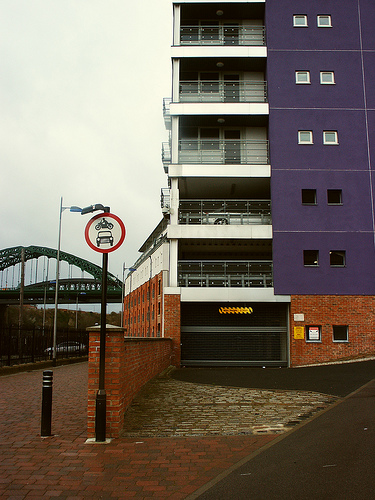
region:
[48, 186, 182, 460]
a street sign on a pole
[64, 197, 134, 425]
a street sign on a metal pole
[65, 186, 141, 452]
a sign on a metal pole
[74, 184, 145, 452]
a sign on a pole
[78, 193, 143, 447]
a circle street sign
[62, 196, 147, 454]
a circle street sign on a pole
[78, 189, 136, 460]
a circle street sign on a metal pole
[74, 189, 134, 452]
a circle sign on a pole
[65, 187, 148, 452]
a circle sign on a metal pole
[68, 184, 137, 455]
a circle sign outside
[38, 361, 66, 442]
a pole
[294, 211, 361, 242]
a purple building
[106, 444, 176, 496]
the ground is made of bricks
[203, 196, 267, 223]
a car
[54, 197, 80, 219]
a street light in the sky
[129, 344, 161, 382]
a brick wall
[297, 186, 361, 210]
windows on the building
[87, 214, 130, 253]
a traffic sign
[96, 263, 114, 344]
a black pole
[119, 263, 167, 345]
a brown and white building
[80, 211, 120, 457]
Street sign with a car and motorcycle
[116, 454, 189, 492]
Sidewalk made of brick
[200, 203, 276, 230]
Silver car parked in garage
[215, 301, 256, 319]
Hazard sign on parking garage door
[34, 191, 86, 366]
Lamp post on sidewalk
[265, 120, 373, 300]
Side of parking garage is purple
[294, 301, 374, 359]
First floor is made of brick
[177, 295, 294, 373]
Parking garage door entrance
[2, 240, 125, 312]
Bridge located behind parking garage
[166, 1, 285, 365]
The building is six stories high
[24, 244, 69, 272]
a green ramp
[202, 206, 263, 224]
a silver car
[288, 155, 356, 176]
a purple building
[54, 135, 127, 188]
The sky is cloudy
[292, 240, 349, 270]
windows on the building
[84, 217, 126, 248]
a traffic sign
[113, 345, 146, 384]
a brick wall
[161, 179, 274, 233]
silver car parked in parking garage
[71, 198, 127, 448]
street sign with motorcycle and automobile on it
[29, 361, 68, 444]
black metal safety pole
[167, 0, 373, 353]
purple sided apartment building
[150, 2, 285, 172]
open balconies on apartment building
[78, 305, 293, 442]
brick wall leading to parking garage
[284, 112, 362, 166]
two white framed windows on purple building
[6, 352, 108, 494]
brick driveway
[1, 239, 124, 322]
green metal arched bridge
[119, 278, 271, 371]
brick parking garage with multiple windows on the back wall